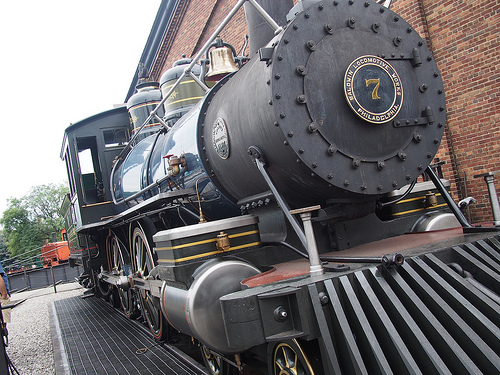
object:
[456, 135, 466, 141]
brick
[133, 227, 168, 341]
wheel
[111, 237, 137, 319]
wheel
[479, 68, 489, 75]
bricks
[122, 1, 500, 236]
building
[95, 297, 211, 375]
tracks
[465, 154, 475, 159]
brick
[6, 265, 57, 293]
fence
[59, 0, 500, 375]
train engine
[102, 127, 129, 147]
window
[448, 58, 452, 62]
brick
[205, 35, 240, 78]
bell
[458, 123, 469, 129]
brick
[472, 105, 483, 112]
brick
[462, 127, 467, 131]
brick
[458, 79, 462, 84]
brick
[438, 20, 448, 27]
brick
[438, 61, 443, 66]
brick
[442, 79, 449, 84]
brick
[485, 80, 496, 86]
brick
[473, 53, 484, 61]
brick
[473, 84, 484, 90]
brick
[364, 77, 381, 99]
number seven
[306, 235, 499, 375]
cattle guard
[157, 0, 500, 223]
wall